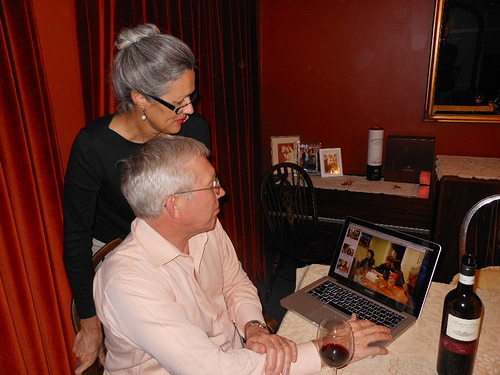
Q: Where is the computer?
A: Table.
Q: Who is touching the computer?
A: Man.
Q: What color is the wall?
A: Red.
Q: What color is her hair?
A: Gray.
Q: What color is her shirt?
A: Black.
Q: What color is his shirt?
A: White.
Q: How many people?
A: Two.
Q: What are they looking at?
A: Computer.